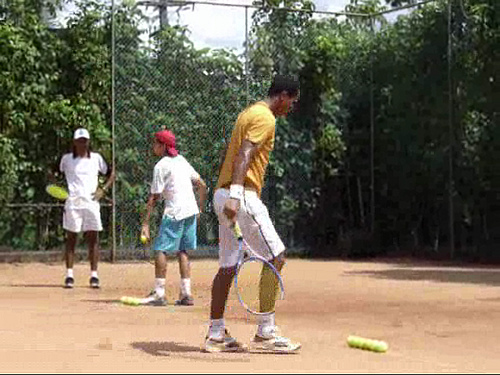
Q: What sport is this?
A: Tennis.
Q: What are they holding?
A: Rackets.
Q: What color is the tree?
A: Green.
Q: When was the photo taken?
A: Daytime.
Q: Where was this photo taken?
A: Tennis court.